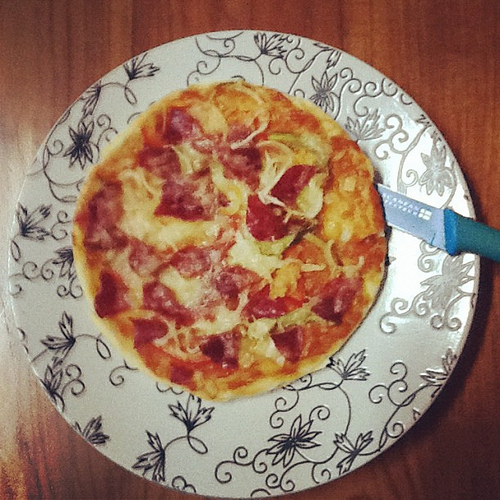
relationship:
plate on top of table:
[9, 32, 483, 500] [3, 1, 499, 498]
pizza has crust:
[70, 82, 388, 405] [229, 302, 373, 398]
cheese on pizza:
[117, 164, 217, 251] [70, 82, 388, 405]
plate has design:
[9, 32, 483, 500] [216, 347, 461, 498]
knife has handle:
[375, 180, 499, 259] [444, 207, 499, 261]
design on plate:
[216, 347, 461, 498] [9, 32, 483, 500]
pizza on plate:
[70, 82, 388, 405] [9, 32, 483, 500]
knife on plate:
[375, 180, 499, 259] [9, 32, 483, 500]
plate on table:
[9, 32, 483, 500] [3, 1, 499, 498]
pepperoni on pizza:
[152, 179, 212, 220] [70, 82, 388, 405]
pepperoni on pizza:
[128, 237, 171, 276] [70, 82, 388, 405]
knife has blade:
[375, 180, 499, 259] [375, 181, 444, 249]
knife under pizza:
[375, 180, 499, 259] [70, 82, 388, 405]